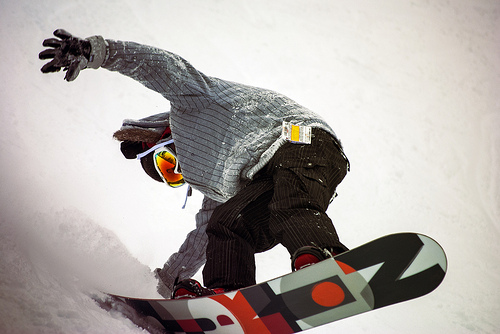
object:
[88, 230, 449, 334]
board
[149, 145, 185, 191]
reflective goggles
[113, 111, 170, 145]
hood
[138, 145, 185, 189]
helmet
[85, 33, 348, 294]
outfit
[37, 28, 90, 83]
glove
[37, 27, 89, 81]
hand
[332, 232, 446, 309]
letter n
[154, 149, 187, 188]
color orange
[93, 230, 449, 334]
decorations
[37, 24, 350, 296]
crouched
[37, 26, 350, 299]
snow gear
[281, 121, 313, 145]
tag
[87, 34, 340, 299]
jacket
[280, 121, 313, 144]
allowance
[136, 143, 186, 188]
snowboarders face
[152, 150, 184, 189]
mirror lens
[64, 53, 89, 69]
snow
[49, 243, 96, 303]
snow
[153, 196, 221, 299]
arm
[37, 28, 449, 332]
trick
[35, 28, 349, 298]
man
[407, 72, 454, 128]
white clouds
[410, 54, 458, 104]
sky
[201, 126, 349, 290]
pants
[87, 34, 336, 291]
shirt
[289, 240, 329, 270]
snow boot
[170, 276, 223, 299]
snow boot